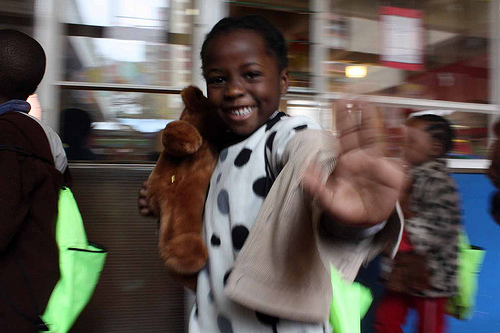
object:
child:
[181, 13, 415, 332]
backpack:
[39, 182, 109, 333]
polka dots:
[214, 185, 234, 219]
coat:
[396, 158, 469, 302]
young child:
[350, 112, 471, 332]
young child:
[0, 24, 76, 331]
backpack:
[321, 262, 376, 333]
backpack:
[446, 230, 488, 321]